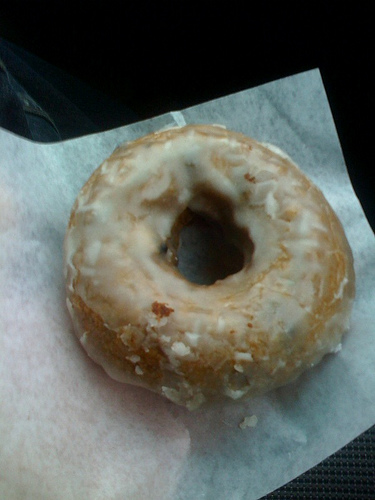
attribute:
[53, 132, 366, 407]
donut — glazed, holed, brown